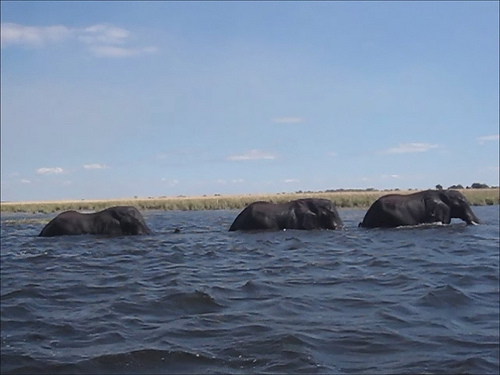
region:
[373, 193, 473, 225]
a grey elephant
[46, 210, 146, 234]
elephant in the water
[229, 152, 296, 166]
clouds in the sky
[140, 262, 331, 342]
the water is blue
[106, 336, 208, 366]
small waves in the water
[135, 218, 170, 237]
the elephants trunk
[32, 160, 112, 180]
the white clouds in the sky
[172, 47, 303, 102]
the sky is clear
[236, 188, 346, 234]
the elephant is wet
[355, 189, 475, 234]
the elephant is standing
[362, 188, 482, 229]
Large elephant in water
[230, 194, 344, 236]
Large elephant in water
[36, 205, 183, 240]
Large elephant in water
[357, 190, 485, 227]
Large elephant is wet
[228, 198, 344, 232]
Large elephant is wet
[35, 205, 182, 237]
Large elephant is wet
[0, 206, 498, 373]
Choppy blue body of water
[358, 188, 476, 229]
Large elephant in front of large elephant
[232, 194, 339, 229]
Large elephant in front of large elephant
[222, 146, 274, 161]
White cloud in blue sky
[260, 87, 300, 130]
part of a cloud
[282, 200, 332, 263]
part of an elephant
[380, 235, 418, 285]
part of a water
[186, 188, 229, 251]
part of a ground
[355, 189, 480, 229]
elephant in the lead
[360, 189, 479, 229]
elephant with tusk showing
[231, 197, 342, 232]
elephant in the second position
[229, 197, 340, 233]
elephant in the center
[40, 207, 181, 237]
elephant in third position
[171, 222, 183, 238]
end of the trunk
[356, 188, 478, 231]
pachyderm in the lead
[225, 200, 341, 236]
pachyderm in second position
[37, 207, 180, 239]
pachyderm in third position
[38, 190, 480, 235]
three elephants in the water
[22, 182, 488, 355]
three elephants walking in water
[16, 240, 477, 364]
choppiness at surface of the water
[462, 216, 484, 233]
tusk of an elephant partially submerged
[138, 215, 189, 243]
partially submerged trunk of an elephant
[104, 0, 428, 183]
blue sky with a few white clouds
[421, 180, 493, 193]
green trees in the far distance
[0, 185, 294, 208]
very flat brown land area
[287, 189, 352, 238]
head of an elephant walking in the water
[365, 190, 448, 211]
back of an elephant walking in the water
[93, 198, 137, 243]
large right ear of an elephant walking in water